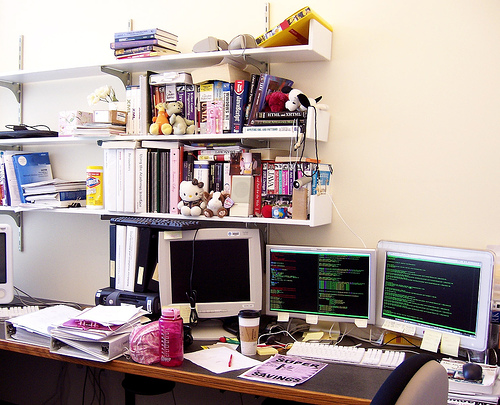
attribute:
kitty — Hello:
[175, 179, 207, 217]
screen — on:
[264, 245, 378, 326]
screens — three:
[157, 229, 494, 355]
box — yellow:
[254, 7, 334, 47]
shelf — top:
[0, 5, 334, 85]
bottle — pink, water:
[158, 305, 182, 367]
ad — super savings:
[238, 352, 328, 387]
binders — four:
[109, 224, 152, 293]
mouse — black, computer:
[460, 364, 481, 381]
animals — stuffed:
[150, 99, 197, 139]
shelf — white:
[0, 106, 330, 146]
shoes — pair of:
[0, 124, 56, 137]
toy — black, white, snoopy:
[280, 87, 321, 113]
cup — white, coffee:
[238, 318, 260, 358]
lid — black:
[236, 310, 258, 318]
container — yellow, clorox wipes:
[83, 165, 103, 211]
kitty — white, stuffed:
[174, 179, 205, 218]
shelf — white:
[0, 196, 334, 229]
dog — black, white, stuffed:
[281, 86, 321, 114]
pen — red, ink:
[227, 355, 233, 367]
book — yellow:
[253, 6, 311, 47]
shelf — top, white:
[0, 19, 332, 79]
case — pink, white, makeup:
[129, 321, 159, 364]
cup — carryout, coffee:
[238, 310, 260, 356]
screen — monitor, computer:
[170, 240, 250, 304]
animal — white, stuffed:
[177, 179, 204, 218]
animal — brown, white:
[199, 186, 235, 220]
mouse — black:
[457, 356, 484, 383]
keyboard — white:
[275, 333, 409, 376]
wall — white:
[357, 44, 484, 224]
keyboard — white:
[281, 334, 411, 372]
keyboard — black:
[101, 211, 202, 234]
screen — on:
[373, 236, 494, 363]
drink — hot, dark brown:
[232, 305, 262, 357]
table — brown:
[13, 304, 427, 404]